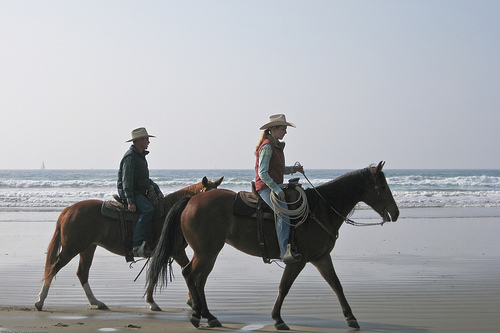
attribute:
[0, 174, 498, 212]
foam — white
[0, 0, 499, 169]
clouds — white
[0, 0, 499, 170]
sky — blue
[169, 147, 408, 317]
horse — brown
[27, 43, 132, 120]
sky — blue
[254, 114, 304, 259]
woman — young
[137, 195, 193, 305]
tail hair — long, black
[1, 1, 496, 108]
sky — blue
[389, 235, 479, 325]
sand — brown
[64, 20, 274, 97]
clouds — white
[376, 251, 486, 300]
sand — wet